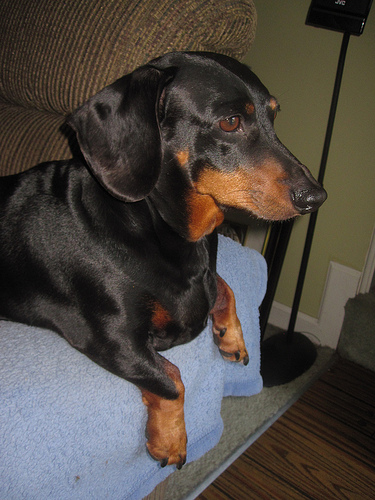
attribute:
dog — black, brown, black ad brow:
[0, 49, 328, 469]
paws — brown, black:
[142, 318, 251, 472]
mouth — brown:
[201, 191, 296, 226]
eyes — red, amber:
[216, 106, 278, 133]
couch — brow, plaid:
[0, 0, 268, 499]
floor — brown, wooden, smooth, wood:
[177, 356, 373, 497]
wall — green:
[239, 0, 374, 350]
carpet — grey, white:
[136, 324, 335, 500]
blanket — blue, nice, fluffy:
[1, 233, 268, 498]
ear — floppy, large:
[61, 61, 172, 203]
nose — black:
[293, 180, 327, 218]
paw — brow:
[209, 314, 249, 368]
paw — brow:
[144, 408, 189, 470]